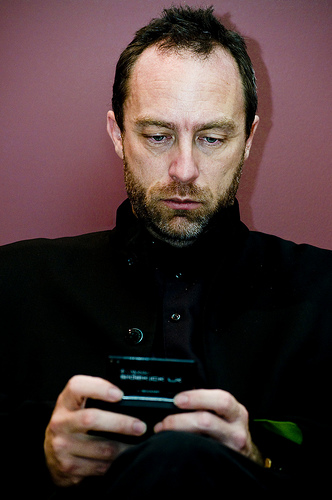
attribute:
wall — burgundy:
[1, 1, 321, 247]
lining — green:
[254, 414, 306, 444]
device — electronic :
[92, 341, 198, 435]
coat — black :
[0, 199, 327, 497]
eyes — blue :
[143, 126, 226, 148]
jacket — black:
[1, 197, 329, 495]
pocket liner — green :
[246, 412, 304, 445]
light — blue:
[127, 323, 146, 343]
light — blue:
[104, 352, 193, 363]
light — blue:
[118, 394, 173, 401]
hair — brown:
[110, 0, 257, 143]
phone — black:
[85, 264, 198, 441]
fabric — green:
[250, 415, 308, 448]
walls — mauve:
[0, 0, 332, 251]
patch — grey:
[185, 216, 208, 238]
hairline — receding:
[113, 17, 249, 122]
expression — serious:
[130, 105, 240, 235]